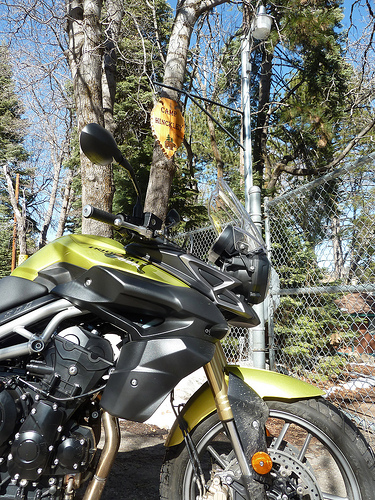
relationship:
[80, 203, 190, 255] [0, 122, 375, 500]
handle bar on motorcycle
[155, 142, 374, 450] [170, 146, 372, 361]
motorcycle by a fence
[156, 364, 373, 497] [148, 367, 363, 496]
tire of motorcycle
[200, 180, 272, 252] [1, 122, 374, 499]
windshield of motorcycle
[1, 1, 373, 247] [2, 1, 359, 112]
sky has clouds